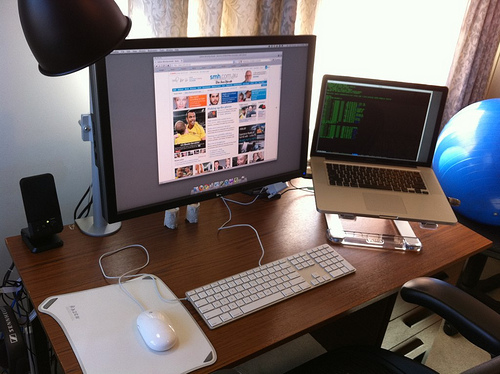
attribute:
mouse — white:
[134, 309, 176, 350]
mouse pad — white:
[53, 278, 209, 373]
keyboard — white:
[187, 245, 354, 328]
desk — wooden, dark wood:
[6, 169, 492, 373]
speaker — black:
[20, 174, 62, 251]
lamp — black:
[18, 2, 137, 77]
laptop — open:
[316, 86, 461, 223]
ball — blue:
[435, 102, 498, 221]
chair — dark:
[285, 286, 497, 373]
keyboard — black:
[323, 162, 431, 194]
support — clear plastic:
[165, 203, 206, 226]